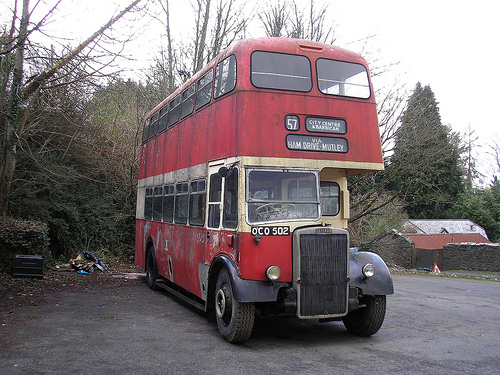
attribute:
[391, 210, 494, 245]
roof — white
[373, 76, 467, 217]
tree — tall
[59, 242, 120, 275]
pile — dirt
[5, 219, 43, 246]
limbs — tree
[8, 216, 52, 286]
bin — garbage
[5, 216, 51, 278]
bin — gray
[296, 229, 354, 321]
grill — black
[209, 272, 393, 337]
wheels — black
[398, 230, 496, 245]
roof — red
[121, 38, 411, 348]
bus — old, double decker, red, white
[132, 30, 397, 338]
bus — red, white, blue, double decker, old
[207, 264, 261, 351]
wheel — double decker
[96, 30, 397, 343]
bus — double decker, old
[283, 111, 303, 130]
number — 57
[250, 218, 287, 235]
plate — license, white, black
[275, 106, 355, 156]
text — white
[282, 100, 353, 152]
background — black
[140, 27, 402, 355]
bus — white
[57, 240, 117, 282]
debris — pile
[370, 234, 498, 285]
wall — stone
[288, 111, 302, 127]
numbers — white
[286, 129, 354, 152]
letters — white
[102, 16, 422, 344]
bus — red